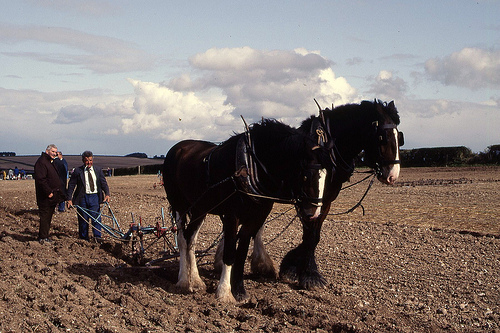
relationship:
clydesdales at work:
[165, 100, 408, 307] [72, 196, 191, 264]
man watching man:
[35, 144, 71, 240] [71, 149, 113, 234]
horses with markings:
[161, 103, 405, 301] [308, 121, 405, 210]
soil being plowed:
[34, 222, 286, 305] [64, 196, 190, 263]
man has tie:
[71, 149, 113, 234] [84, 167, 98, 193]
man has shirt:
[71, 149, 113, 234] [84, 166, 96, 194]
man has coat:
[71, 149, 113, 234] [73, 166, 108, 199]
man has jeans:
[71, 149, 113, 234] [78, 194, 101, 242]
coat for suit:
[73, 166, 108, 199] [67, 165, 112, 209]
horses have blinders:
[161, 103, 405, 301] [373, 124, 407, 151]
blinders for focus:
[373, 124, 407, 151] [307, 157, 333, 176]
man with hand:
[35, 144, 71, 240] [46, 190, 56, 199]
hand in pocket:
[46, 190, 56, 199] [45, 189, 67, 201]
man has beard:
[35, 144, 71, 240] [50, 154, 60, 161]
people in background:
[34, 143, 111, 240] [51, 60, 188, 266]